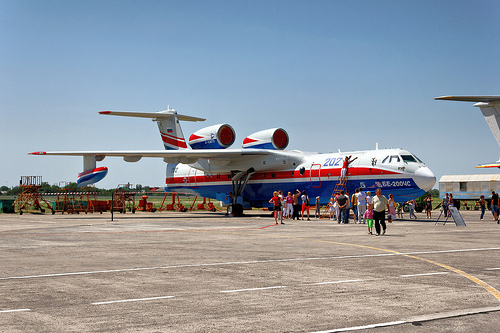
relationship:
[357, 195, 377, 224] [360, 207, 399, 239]
person wearing pants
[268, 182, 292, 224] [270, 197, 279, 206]
person wearing shirt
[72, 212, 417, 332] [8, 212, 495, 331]
lines on tarmac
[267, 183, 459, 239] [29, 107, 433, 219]
people exiting plane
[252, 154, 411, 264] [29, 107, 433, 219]
people leaving plane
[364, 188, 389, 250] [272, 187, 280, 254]
person wearing black shorts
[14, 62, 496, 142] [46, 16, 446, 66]
no clouds in sky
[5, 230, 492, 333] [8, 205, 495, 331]
parts of tarmac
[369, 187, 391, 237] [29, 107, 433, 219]
person are near plane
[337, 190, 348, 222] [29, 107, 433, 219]
people are near plane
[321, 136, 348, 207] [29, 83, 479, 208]
numbers are on plane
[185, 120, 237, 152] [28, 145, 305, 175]
engine are on top of wing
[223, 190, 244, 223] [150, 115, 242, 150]
person standing under wing